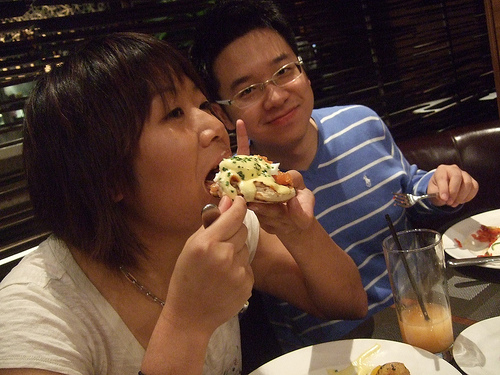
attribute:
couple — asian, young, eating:
[14, 28, 463, 373]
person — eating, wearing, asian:
[2, 47, 372, 343]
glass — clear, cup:
[381, 221, 457, 350]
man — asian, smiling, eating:
[189, 0, 467, 314]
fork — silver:
[384, 186, 440, 206]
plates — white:
[243, 316, 499, 372]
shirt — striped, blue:
[212, 101, 444, 341]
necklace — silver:
[105, 247, 166, 307]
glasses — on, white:
[214, 61, 307, 111]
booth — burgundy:
[390, 120, 498, 222]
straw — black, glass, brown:
[385, 212, 431, 320]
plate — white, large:
[242, 335, 466, 374]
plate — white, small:
[449, 310, 499, 374]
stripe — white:
[320, 133, 385, 176]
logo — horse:
[357, 170, 377, 187]